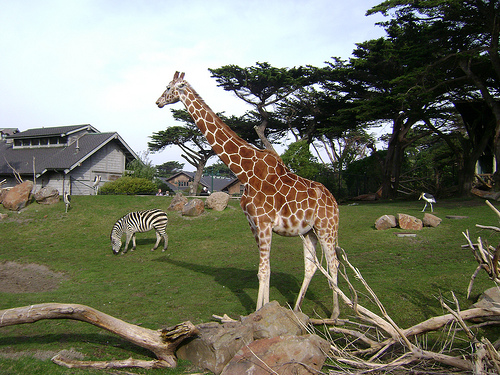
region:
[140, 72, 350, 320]
a fully grown adult giraffe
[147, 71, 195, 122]
the head of a giraffe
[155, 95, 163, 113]
the mouth of a giraffe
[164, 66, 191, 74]
the horn of a giraffe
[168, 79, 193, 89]
the ear of a giraffe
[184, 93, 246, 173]
the neck of a giraffe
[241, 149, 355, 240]
the body of a giraffe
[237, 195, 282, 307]
the front legs of a giraffe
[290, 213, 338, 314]
the the back legs of a giraffe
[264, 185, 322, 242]
the belly of a giraffe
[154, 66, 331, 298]
this is a giraffe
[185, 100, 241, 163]
this is the neck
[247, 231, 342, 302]
these are the legs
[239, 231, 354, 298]
the legs are long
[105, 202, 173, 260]
this is a zebra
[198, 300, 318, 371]
this is a rock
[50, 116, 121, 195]
this s a house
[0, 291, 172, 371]
this is a log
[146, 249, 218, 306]
this is the grass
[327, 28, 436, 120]
this is the tree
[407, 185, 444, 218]
This is a bird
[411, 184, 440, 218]
This is a bird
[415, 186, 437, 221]
This is a bird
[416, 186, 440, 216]
This is a bird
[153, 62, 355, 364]
This is a giraffe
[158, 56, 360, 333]
This is a giraffe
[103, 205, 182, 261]
This is a zebra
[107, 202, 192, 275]
This is a zebra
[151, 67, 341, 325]
a tall giraffe looking off into the distance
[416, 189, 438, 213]
small white long legged bird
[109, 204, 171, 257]
a grazing zebra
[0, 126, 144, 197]
grey painted structure with greyish roof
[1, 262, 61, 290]
small dirt patch with no grass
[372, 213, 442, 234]
three orange colored stones in field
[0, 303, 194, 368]
dead decorative tree limb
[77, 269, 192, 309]
trampled short green grass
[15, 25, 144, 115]
very light blue sky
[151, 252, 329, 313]
shadow of a giraffe on grass